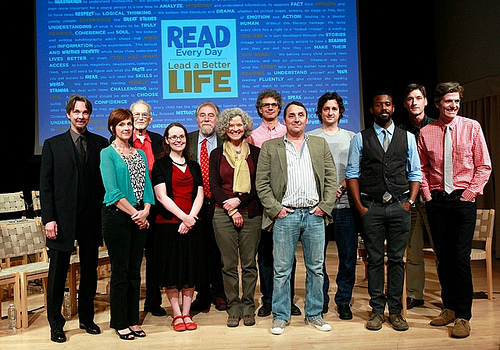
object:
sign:
[165, 25, 231, 92]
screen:
[32, 1, 366, 156]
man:
[39, 94, 109, 343]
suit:
[39, 130, 109, 326]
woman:
[99, 108, 156, 341]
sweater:
[99, 143, 156, 207]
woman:
[150, 121, 212, 331]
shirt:
[151, 154, 205, 223]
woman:
[208, 107, 265, 327]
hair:
[214, 107, 253, 140]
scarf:
[222, 138, 251, 195]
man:
[255, 101, 336, 336]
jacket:
[255, 134, 338, 232]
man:
[344, 91, 424, 332]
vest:
[359, 126, 410, 201]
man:
[416, 80, 492, 337]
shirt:
[416, 116, 493, 203]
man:
[250, 89, 301, 318]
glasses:
[262, 103, 277, 107]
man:
[187, 100, 229, 313]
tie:
[199, 138, 212, 200]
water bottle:
[7, 302, 20, 334]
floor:
[2, 237, 497, 349]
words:
[45, 0, 163, 93]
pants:
[46, 227, 99, 328]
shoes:
[171, 314, 197, 331]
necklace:
[171, 157, 188, 166]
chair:
[421, 208, 496, 301]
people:
[99, 107, 155, 340]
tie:
[442, 126, 455, 195]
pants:
[424, 190, 476, 320]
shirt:
[345, 120, 423, 182]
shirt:
[246, 120, 287, 149]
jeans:
[272, 207, 326, 324]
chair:
[0, 191, 52, 332]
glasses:
[167, 134, 186, 140]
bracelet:
[229, 208, 239, 216]